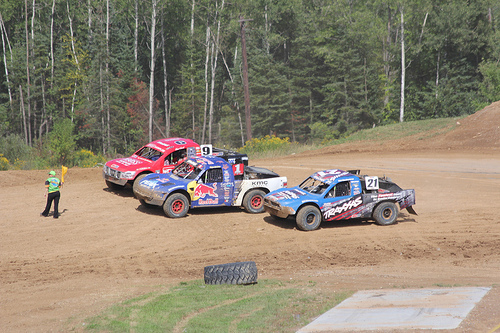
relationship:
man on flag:
[41, 170, 63, 218] [52, 159, 67, 181]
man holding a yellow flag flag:
[41, 170, 63, 218] [61, 165, 68, 185]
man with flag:
[41, 170, 63, 218] [58, 157, 70, 180]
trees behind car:
[4, 5, 494, 166] [261, 168, 418, 231]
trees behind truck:
[4, 5, 494, 166] [134, 157, 288, 214]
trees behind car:
[4, 5, 494, 166] [101, 137, 233, 194]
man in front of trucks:
[41, 170, 63, 218] [146, 133, 408, 245]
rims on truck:
[160, 196, 195, 224] [119, 128, 176, 165]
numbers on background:
[187, 140, 219, 159] [15, 24, 489, 324]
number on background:
[225, 160, 248, 178] [230, 160, 240, 171]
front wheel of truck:
[294, 204, 322, 231] [277, 160, 414, 248]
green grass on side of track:
[73, 277, 351, 331] [3, 233, 498, 286]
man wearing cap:
[42, 167, 63, 218] [23, 164, 53, 178]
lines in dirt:
[56, 246, 162, 279] [1, 93, 483, 329]